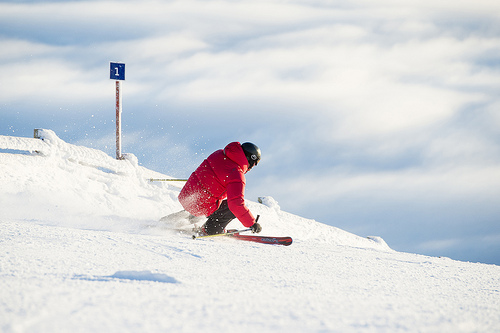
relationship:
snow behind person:
[42, 224, 316, 327] [177, 141, 261, 237]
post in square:
[94, 52, 178, 180] [110, 62, 126, 80]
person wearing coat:
[177, 141, 261, 237] [177, 141, 256, 228]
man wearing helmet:
[192, 137, 339, 321] [233, 123, 283, 171]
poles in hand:
[150, 161, 307, 261] [226, 184, 286, 244]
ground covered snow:
[29, 132, 459, 313] [42, 224, 316, 327]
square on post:
[88, 47, 139, 95] [94, 52, 178, 180]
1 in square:
[88, 44, 147, 83] [99, 41, 147, 105]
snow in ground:
[42, 224, 316, 327] [35, 120, 483, 323]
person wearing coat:
[153, 117, 340, 307] [177, 141, 256, 228]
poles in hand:
[150, 161, 307, 261] [229, 177, 268, 233]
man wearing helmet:
[192, 137, 339, 321] [243, 130, 290, 187]